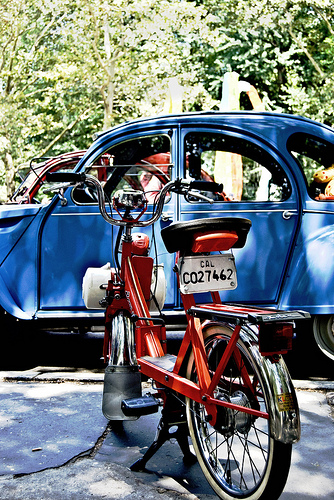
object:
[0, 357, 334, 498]
sidewalk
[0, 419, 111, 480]
crack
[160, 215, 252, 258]
seat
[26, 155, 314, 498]
bike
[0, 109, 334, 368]
blue car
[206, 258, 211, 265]
letter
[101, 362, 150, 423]
flap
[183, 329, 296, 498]
wheel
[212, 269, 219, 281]
number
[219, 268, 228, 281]
number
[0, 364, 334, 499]
ground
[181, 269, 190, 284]
letter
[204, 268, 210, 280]
number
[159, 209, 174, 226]
silver handle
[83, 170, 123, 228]
silver handle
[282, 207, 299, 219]
silver handle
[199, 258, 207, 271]
letter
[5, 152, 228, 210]
car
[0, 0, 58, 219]
trees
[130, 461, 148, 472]
gaps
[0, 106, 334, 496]
area